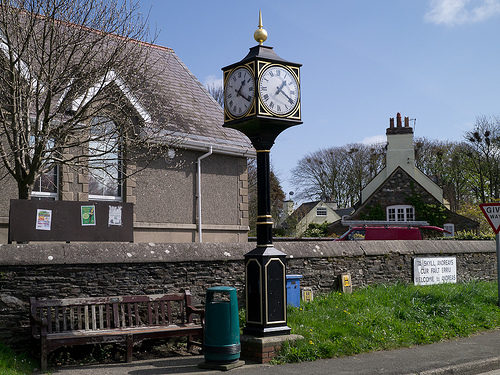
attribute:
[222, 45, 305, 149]
clock — box shaped, black, white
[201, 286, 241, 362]
trashcan — green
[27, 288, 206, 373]
bench — brown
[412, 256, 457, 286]
sign — white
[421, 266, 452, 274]
letters — black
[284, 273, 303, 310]
box — blue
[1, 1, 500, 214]
sky — clear, blue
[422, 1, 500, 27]
cloud — white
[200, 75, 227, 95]
cloud — white